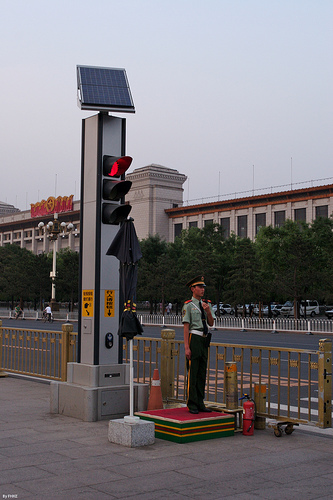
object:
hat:
[187, 274, 206, 287]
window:
[237, 215, 247, 240]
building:
[0, 163, 333, 258]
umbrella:
[106, 216, 145, 421]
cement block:
[107, 416, 156, 447]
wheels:
[273, 427, 282, 437]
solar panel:
[74, 64, 134, 112]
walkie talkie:
[205, 332, 213, 349]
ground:
[267, 327, 290, 343]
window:
[294, 209, 305, 224]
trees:
[0, 211, 332, 323]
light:
[101, 154, 134, 220]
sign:
[102, 286, 117, 317]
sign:
[79, 288, 95, 318]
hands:
[185, 349, 192, 360]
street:
[2, 317, 330, 407]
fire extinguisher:
[239, 393, 257, 436]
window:
[236, 214, 246, 238]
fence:
[0, 314, 333, 429]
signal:
[105, 152, 134, 177]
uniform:
[181, 294, 217, 412]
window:
[220, 217, 230, 239]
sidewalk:
[0, 374, 333, 500]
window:
[274, 210, 286, 226]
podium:
[134, 405, 235, 444]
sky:
[0, 1, 333, 212]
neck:
[192, 295, 202, 301]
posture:
[182, 275, 216, 416]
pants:
[186, 330, 213, 414]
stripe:
[186, 329, 193, 405]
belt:
[188, 329, 209, 338]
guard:
[181, 269, 218, 414]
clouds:
[0, 0, 332, 210]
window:
[173, 223, 182, 242]